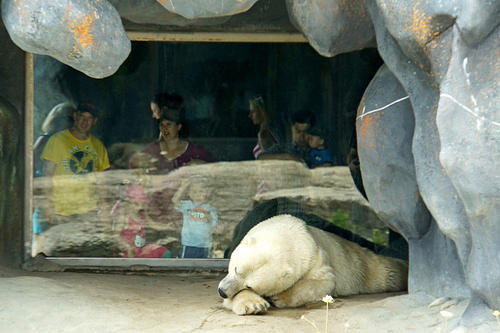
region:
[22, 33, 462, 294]
picture taken at a zoo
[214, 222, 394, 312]
white polar bear sleeping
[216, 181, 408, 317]
white polar bear covered with blanket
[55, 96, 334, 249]
people looking into polar bear cage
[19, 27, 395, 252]
window looking into polar bear cage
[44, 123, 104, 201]
man with a yellow t-shirt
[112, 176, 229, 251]
children looking into polar bear cave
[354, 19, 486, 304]
grey rocks and boulders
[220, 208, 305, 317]
polar bears head resting on it's paw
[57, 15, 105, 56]
yellow paint on rocks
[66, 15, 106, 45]
Beautiful orange rock spots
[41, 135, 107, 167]
A yellow decorated shirt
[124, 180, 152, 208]
A beautiful pink cap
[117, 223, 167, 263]
A short red dress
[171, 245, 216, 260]
A stripped navy pant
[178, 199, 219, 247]
A white baby tee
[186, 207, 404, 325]
A big white bear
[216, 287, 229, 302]
A black small nose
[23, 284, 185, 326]
A clean spotless surface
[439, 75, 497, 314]
A big grey rock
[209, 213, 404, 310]
the bear is on the floor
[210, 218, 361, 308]
the bear is white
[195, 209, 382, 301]
the bear is asleep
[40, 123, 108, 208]
the shirt is yellow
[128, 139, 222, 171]
the shirt is prurple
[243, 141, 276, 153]
theshirtis striped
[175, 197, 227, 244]
the shirt is white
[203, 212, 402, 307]
the bear is in a zoo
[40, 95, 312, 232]
8 people are in the zoo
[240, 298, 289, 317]
the claws are sharp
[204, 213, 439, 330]
this is a dog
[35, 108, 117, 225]
this is a person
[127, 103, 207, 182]
this is a person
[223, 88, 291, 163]
this is a person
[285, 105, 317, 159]
this is a person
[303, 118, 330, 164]
this is a child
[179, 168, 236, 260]
this is a child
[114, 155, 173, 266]
this is a child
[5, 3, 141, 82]
this is a rock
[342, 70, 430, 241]
this is a rock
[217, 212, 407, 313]
White polar bear sleeping at zoo.